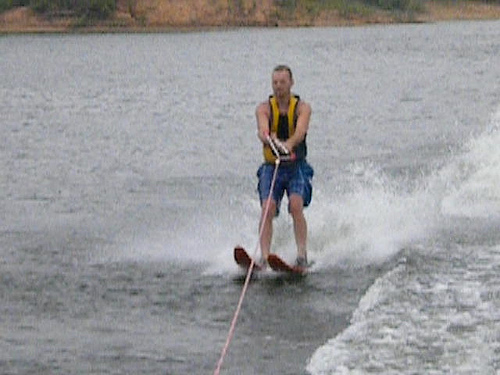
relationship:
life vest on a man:
[260, 91, 307, 163] [252, 56, 321, 270]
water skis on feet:
[234, 246, 306, 273] [237, 242, 320, 274]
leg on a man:
[257, 163, 283, 272] [255, 64, 314, 272]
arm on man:
[285, 102, 315, 152] [252, 56, 321, 270]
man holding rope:
[255, 64, 312, 269] [214, 145, 284, 373]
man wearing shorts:
[255, 64, 312, 269] [278, 161, 314, 200]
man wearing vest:
[255, 64, 312, 269] [261, 93, 303, 159]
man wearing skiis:
[255, 64, 312, 269] [224, 238, 314, 283]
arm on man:
[287, 104, 312, 144] [245, 65, 314, 268]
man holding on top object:
[255, 64, 312, 269] [263, 129, 295, 165]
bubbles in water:
[311, 273, 464, 373] [3, 25, 498, 372]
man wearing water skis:
[255, 64, 314, 272] [236, 242, 321, 282]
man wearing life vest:
[255, 64, 312, 269] [263, 93, 300, 163]